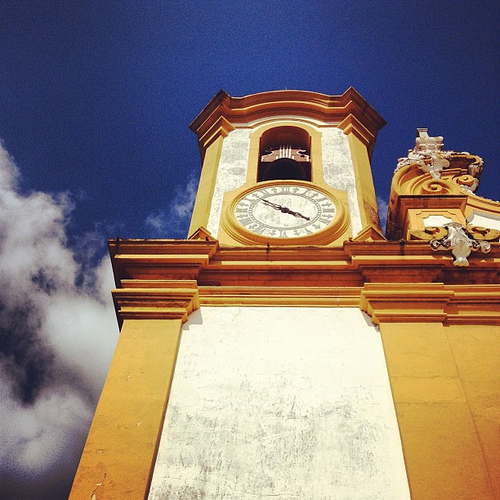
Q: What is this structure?
A: A clock tower.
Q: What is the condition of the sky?
A: Blue and bright with areas of thick clouds.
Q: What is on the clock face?
A: Roman numerals and a minute and hour hand.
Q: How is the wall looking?
A: Brown.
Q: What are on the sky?
A: Clouds.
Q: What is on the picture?
A: Building.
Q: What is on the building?
A: Clock.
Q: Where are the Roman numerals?
A: On the clock face.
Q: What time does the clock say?
A: 4:50.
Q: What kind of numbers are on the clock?
A: Roman numerals.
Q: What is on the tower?
A: A clock.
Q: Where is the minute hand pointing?
A: At 10.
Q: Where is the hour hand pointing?
A: Between four and five.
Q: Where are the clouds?
A: Behind the tower.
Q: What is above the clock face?
A: Bell tower.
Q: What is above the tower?
A: Blue sky.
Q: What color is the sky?
A: Blue.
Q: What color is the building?
A: Golden.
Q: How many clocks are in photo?
A: One.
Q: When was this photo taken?
A: In the daytime.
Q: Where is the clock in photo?
A: On a building.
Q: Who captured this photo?
A: A photographer.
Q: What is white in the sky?
A: Clouds.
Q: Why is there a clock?
A: To show the time.